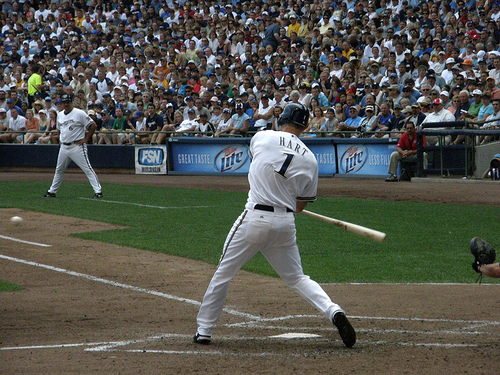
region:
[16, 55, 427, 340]
fans watching a baseball game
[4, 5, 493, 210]
a large crowd at the baseball game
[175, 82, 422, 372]
the batter using proper batting form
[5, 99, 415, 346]
a batter named Hart is about to hit the ball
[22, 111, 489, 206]
park advertisements in the stadium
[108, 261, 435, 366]
homebase beneath the batters feet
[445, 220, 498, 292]
the catcher's glove can barely be seen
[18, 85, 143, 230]
this player is observing the action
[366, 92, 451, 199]
a man in the red shirt is watching the game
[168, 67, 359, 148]
the batter is wearing a black helmet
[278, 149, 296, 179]
The number 1 on the batter's shirt.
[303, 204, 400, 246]
The wooden bat in the batter's hand.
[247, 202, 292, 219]
The black belt the batter is wearing.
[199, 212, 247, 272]
The black stripe on the batter's pants.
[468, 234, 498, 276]
The black glove the catcher is wearing.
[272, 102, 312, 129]
The black helmet the batter is wearing.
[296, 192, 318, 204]
The stripe on the batter's shirt sleeve.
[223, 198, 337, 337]
The white pants the batter is wearing.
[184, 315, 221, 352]
The left sneaker of the batter.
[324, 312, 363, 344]
The right sneaker of the batter.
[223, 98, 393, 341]
baseball player at bat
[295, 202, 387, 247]
wooden bat in player's hand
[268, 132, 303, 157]
name on back of jersey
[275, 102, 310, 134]
helmet on player's head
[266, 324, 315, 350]
base on home plate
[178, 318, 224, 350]
cleat on player's foot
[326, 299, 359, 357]
cleat on player's foot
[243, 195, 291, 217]
belt on player's pants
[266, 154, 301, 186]
number on player's jersey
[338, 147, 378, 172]
miller lite symbol on back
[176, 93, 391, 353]
right handed batter at home plate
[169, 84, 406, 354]
batter swinging at a ball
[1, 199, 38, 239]
the baseball in flight toward home plate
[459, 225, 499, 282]
the catcher's glove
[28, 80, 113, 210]
first base coach with one foot in coach's box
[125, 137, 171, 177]
a banner promoting FSN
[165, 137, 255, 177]
a promotional message for beer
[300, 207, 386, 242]
a light colored baseball bat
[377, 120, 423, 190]
a person in the playing field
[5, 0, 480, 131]
a packed house watching the game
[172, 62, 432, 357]
A batter getting ready to swing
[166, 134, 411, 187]
miller lite advertisment on wall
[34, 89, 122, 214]
a player stands waiting on the field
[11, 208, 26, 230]
a white ball moving through the air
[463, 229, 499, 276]
the black mitt of the catcher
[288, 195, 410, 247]
a white long bat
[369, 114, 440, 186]
A man in red shirt next to advertisement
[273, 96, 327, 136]
Black batting helmet on head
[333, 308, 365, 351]
black bottom of a shoe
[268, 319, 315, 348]
white home plate base